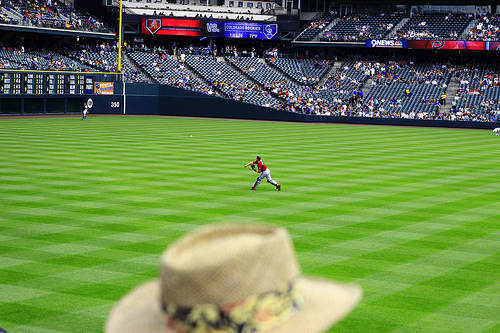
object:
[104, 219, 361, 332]
hat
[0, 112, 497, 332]
field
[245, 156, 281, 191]
catcher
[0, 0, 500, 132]
stand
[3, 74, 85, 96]
scoreboard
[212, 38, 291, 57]
box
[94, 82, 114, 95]
sign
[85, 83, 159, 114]
wall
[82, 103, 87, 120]
outfielder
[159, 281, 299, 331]
band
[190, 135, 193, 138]
ball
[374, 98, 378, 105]
spectator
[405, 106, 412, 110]
seat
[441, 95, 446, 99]
shirt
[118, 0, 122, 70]
pole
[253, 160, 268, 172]
jersey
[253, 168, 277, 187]
pants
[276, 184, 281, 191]
cleat